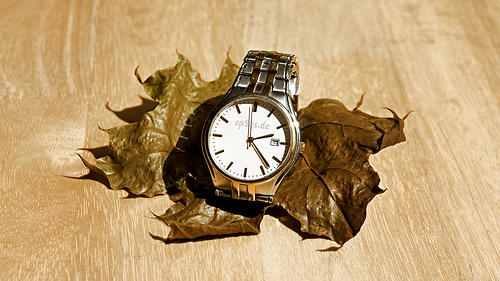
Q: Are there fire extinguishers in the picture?
A: No, there are no fire extinguishers.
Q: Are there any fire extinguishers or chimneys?
A: No, there are no fire extinguishers or chimneys.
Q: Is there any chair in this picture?
A: No, there are no chairs.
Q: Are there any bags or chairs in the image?
A: No, there are no chairs or bags.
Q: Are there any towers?
A: No, there are no towers.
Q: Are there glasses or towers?
A: No, there are no towers or glasses.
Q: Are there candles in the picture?
A: No, there are no candles.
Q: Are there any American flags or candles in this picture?
A: No, there are no candles or American flags.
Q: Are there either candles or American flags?
A: No, there are no candles or American flags.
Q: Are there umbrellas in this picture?
A: No, there are no umbrellas.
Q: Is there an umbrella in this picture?
A: No, there are no umbrellas.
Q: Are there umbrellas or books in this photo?
A: No, there are no umbrellas or books.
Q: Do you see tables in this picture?
A: Yes, there is a table.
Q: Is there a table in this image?
A: Yes, there is a table.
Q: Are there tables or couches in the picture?
A: Yes, there is a table.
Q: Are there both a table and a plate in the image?
A: No, there is a table but no plates.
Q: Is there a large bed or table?
A: Yes, there is a large table.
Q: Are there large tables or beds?
A: Yes, there is a large table.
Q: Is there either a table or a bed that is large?
A: Yes, the table is large.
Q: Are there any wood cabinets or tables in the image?
A: Yes, there is a wood table.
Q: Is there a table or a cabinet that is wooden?
A: Yes, the table is wooden.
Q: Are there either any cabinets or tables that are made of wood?
A: Yes, the table is made of wood.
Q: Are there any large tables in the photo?
A: Yes, there is a large table.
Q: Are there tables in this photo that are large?
A: Yes, there is a table that is large.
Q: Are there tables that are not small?
A: Yes, there is a large table.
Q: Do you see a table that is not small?
A: Yes, there is a large table.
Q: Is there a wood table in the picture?
A: Yes, there is a wood table.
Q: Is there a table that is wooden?
A: Yes, there is a table that is wooden.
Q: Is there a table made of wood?
A: Yes, there is a table that is made of wood.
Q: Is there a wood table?
A: Yes, there is a table that is made of wood.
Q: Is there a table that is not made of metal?
A: Yes, there is a table that is made of wood.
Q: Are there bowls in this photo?
A: No, there are no bowls.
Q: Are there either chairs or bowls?
A: No, there are no bowls or chairs.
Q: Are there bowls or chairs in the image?
A: No, there are no bowls or chairs.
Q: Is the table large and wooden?
A: Yes, the table is large and wooden.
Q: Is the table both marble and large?
A: No, the table is large but wooden.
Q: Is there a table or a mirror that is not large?
A: No, there is a table but it is large.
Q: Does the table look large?
A: Yes, the table is large.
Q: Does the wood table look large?
A: Yes, the table is large.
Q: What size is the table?
A: The table is large.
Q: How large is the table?
A: The table is large.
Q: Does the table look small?
A: No, the table is large.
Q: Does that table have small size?
A: No, the table is large.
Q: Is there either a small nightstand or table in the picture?
A: No, there is a table but it is large.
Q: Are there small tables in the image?
A: No, there is a table but it is large.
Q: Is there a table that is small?
A: No, there is a table but it is large.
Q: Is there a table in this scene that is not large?
A: No, there is a table but it is large.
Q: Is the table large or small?
A: The table is large.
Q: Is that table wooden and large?
A: Yes, the table is wooden and large.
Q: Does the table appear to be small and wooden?
A: No, the table is wooden but large.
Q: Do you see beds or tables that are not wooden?
A: No, there is a table but it is wooden.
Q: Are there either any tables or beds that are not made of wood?
A: No, there is a table but it is made of wood.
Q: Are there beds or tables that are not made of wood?
A: No, there is a table but it is made of wood.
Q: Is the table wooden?
A: Yes, the table is wooden.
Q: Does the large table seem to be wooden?
A: Yes, the table is wooden.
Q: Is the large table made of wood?
A: Yes, the table is made of wood.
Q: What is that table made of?
A: The table is made of wood.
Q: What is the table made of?
A: The table is made of wood.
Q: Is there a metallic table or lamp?
A: No, there is a table but it is wooden.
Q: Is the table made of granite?
A: No, the table is made of wood.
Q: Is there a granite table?
A: No, there is a table but it is made of wood.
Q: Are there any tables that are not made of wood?
A: No, there is a table but it is made of wood.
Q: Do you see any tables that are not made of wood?
A: No, there is a table but it is made of wood.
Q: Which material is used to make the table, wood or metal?
A: The table is made of wood.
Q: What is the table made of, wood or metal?
A: The table is made of wood.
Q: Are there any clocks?
A: Yes, there is a clock.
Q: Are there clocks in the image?
A: Yes, there is a clock.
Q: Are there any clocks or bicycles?
A: Yes, there is a clock.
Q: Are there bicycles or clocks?
A: Yes, there is a clock.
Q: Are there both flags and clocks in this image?
A: No, there is a clock but no flags.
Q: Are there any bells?
A: No, there are no bells.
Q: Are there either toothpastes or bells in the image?
A: No, there are no bells or toothpastes.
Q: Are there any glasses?
A: No, there are no glasses.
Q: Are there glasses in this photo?
A: No, there are no glasses.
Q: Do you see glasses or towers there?
A: No, there are no glasses or towers.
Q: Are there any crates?
A: No, there are no crates.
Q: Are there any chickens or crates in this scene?
A: No, there are no crates or chickens.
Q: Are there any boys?
A: No, there are no boys.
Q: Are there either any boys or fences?
A: No, there are no boys or fences.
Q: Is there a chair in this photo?
A: No, there are no chairs.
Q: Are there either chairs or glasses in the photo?
A: No, there are no chairs or glasses.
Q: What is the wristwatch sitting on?
A: The wristwatch is sitting on the leaf.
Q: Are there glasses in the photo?
A: No, there are no glasses.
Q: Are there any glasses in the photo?
A: No, there are no glasses.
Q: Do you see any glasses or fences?
A: No, there are no glasses or fences.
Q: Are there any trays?
A: No, there are no trays.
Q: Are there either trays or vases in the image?
A: No, there are no trays or vases.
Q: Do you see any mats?
A: No, there are no mats.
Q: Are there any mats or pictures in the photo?
A: No, there are no mats or pictures.